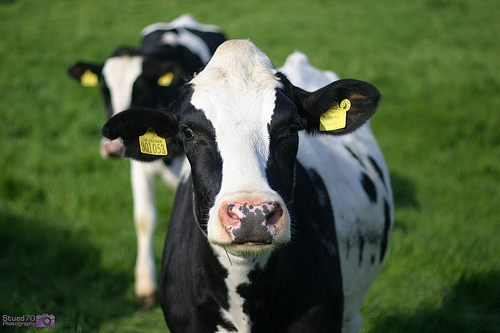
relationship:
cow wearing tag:
[64, 10, 229, 311] [79, 68, 99, 88]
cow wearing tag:
[64, 10, 229, 311] [158, 70, 174, 86]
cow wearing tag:
[99, 35, 398, 330] [136, 125, 169, 156]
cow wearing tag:
[99, 35, 398, 330] [316, 98, 352, 133]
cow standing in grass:
[64, 10, 229, 311] [2, 1, 484, 329]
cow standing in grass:
[99, 35, 398, 330] [2, 1, 484, 329]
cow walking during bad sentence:
[64, 10, 229, 311] [432, 269, 445, 281]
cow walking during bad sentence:
[99, 35, 398, 330] [432, 269, 445, 281]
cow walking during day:
[64, 10, 229, 311] [2, 2, 484, 329]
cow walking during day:
[99, 35, 398, 330] [2, 2, 484, 329]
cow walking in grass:
[64, 10, 229, 311] [2, 1, 484, 329]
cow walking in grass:
[99, 35, 398, 330] [2, 1, 484, 329]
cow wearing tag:
[64, 10, 229, 311] [154, 70, 175, 87]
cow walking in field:
[64, 10, 229, 311] [0, 0, 499, 332]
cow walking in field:
[99, 35, 398, 330] [0, 0, 499, 332]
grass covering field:
[2, 1, 484, 329] [0, 0, 499, 332]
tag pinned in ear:
[136, 125, 169, 156] [99, 103, 182, 163]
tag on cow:
[136, 125, 169, 156] [99, 35, 398, 330]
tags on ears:
[128, 90, 359, 165] [88, 72, 388, 166]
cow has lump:
[99, 35, 398, 330] [210, 33, 270, 66]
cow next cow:
[64, 10, 229, 311] [99, 35, 398, 330]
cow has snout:
[99, 35, 398, 330] [217, 194, 287, 233]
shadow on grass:
[8, 206, 130, 328] [4, 147, 124, 328]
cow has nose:
[99, 35, 398, 330] [219, 194, 288, 233]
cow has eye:
[99, 35, 398, 330] [276, 124, 298, 149]